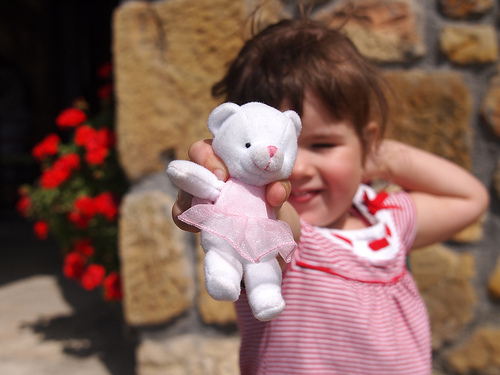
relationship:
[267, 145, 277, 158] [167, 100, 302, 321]
pink nose of bear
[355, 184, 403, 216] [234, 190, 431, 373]
bow on shirt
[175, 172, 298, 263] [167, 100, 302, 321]
tutu on bear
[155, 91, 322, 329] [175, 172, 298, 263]
bear in tutu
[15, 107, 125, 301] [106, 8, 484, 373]
flowers next to wall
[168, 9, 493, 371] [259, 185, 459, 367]
girl wearing dress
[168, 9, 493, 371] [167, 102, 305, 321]
girl holding bear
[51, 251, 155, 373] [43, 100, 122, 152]
pot holding flower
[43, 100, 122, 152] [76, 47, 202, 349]
flower next to wall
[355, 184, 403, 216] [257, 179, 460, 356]
bow on dress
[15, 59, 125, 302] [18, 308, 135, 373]
flowers are casting shadow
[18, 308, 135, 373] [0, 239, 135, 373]
shadow on ground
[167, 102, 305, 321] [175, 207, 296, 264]
bear wearing skirt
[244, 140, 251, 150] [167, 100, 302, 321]
eye on bear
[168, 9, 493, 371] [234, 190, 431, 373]
girl wearing shirt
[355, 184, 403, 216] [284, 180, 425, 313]
bow on shirt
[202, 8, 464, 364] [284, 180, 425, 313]
girl wearing shirt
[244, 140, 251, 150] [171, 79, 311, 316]
eye on bear